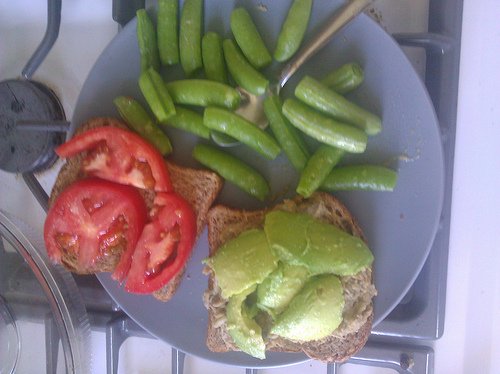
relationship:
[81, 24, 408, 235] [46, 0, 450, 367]
greens on top of plate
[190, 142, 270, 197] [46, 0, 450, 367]
greens top of plate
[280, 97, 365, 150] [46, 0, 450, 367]
greens top of plate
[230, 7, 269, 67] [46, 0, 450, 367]
greens top of plate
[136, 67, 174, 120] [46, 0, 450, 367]
greens top of plate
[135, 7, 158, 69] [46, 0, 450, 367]
greens top of plate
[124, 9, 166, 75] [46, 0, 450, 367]
bean on plate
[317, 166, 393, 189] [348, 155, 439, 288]
green bean on plate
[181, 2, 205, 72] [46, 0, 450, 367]
green bean on plate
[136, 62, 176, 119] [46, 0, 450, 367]
green bean on plate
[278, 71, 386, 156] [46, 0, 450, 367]
greens on plate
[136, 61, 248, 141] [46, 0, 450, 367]
greens on plate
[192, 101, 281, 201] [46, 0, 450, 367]
greens on plate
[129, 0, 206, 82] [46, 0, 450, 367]
greens on plate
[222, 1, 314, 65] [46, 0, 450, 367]
greens on plate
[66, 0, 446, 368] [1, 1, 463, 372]
dish on burner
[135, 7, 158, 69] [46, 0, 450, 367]
greens on top of plate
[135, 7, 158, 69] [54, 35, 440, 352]
greens on plate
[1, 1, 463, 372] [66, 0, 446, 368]
burner under a dish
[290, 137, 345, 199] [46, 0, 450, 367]
bean on plate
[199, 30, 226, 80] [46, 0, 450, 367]
green bean on plate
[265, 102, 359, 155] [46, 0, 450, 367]
green bean on plate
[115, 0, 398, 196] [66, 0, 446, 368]
green beans on top of dish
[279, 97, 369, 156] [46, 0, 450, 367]
green bean on top of plate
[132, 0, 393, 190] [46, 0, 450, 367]
green beans on top of plate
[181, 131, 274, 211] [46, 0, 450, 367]
green bean on top of plate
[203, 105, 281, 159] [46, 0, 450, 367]
greenbean on top of plate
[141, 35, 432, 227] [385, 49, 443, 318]
greens on top of plate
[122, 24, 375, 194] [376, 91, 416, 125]
greens on top of plate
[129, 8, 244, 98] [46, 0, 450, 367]
greens on top of plate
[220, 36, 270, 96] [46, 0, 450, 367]
green bean on top of plate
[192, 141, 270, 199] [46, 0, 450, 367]
green bean on top of plate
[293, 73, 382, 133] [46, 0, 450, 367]
green bean on top of plate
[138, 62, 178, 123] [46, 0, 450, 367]
green bean on top of plate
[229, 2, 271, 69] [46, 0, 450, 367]
green bean on top of plate